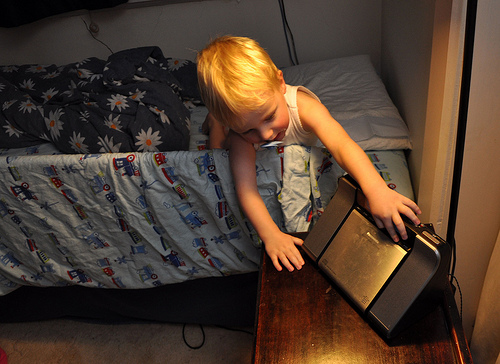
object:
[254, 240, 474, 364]
table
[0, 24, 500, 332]
picture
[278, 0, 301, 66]
cable wire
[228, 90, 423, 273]
arms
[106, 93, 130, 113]
flowers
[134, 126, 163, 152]
flowers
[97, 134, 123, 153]
flowers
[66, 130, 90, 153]
flowers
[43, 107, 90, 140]
flowers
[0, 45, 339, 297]
comforter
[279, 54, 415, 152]
pillow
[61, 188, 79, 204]
white blanket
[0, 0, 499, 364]
room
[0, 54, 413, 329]
bed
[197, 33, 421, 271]
boy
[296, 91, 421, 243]
arm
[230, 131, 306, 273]
arm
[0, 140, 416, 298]
blanket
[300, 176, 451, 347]
radio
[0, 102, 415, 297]
sheet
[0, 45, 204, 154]
blanket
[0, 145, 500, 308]
front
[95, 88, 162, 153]
pattern